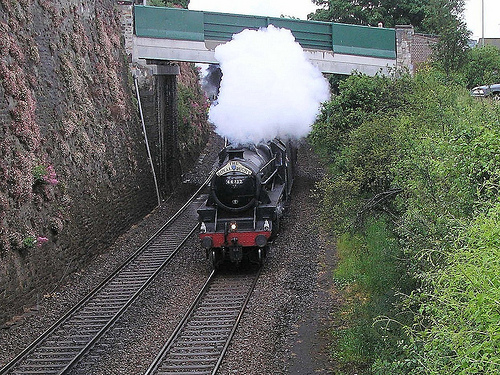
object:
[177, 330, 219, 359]
cross tie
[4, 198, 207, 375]
tie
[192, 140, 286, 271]
engine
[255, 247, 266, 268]
wheels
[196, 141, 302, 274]
train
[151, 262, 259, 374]
tie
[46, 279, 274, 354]
gravel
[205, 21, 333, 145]
cloud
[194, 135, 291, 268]
locomotive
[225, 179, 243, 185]
numbers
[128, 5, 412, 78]
overpass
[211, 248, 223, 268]
wheels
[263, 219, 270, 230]
letter a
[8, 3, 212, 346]
rock wall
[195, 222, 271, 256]
bumper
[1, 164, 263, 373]
rails